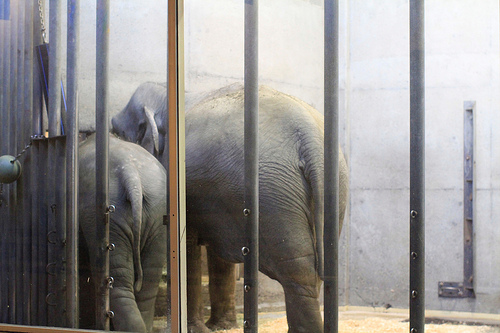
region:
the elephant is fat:
[196, 77, 321, 293]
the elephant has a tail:
[119, 191, 152, 295]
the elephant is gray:
[196, 109, 226, 186]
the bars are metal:
[401, 2, 428, 322]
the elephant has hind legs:
[112, 257, 156, 329]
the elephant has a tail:
[289, 161, 324, 281]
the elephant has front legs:
[188, 249, 241, 324]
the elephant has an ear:
[129, 99, 164, 151]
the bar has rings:
[236, 194, 266, 329]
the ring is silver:
[234, 200, 259, 225]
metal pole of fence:
[405, 5, 430, 330]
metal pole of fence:
[314, 0, 345, 330]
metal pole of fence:
[245, 0, 267, 327]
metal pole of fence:
[150, 1, 192, 329]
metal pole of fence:
[84, 0, 121, 326]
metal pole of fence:
[66, 3, 93, 328]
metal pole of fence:
[47, 5, 61, 325]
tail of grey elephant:
[297, 165, 334, 272]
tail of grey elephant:
[115, 187, 150, 291]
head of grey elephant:
[107, 69, 164, 156]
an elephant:
[179, 131, 339, 259]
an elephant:
[149, 125, 291, 325]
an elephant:
[183, 188, 256, 319]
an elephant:
[202, 176, 302, 318]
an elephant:
[162, 207, 235, 302]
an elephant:
[148, 94, 244, 284]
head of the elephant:
[118, 85, 179, 156]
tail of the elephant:
[305, 131, 340, 291]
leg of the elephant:
[266, 257, 318, 331]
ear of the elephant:
[127, 103, 169, 159]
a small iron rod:
[396, 19, 447, 328]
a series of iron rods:
[26, 43, 488, 298]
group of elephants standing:
[7, 36, 312, 330]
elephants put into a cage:
[36, 15, 491, 299]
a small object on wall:
[431, 263, 489, 303]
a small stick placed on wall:
[447, 101, 499, 292]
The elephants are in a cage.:
[6, 15, 493, 330]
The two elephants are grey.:
[72, 67, 367, 329]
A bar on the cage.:
[227, 8, 273, 328]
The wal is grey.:
[360, 108, 392, 198]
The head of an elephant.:
[110, 70, 175, 160]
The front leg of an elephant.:
[200, 247, 241, 330]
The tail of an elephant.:
[111, 173, 153, 303]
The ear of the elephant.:
[130, 95, 165, 161]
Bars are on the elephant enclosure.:
[6, 0, 496, 330]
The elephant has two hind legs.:
[83, 210, 179, 332]